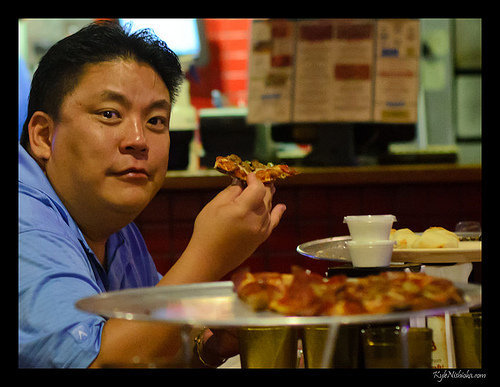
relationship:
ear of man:
[28, 110, 54, 158] [19, 20, 287, 368]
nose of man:
[120, 115, 148, 154] [19, 20, 287, 368]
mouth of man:
[108, 164, 154, 182] [19, 20, 287, 368]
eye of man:
[96, 108, 121, 121] [19, 20, 287, 368]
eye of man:
[144, 116, 168, 126] [19, 20, 287, 368]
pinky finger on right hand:
[268, 202, 288, 233] [195, 169, 286, 271]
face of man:
[68, 60, 170, 209] [19, 20, 287, 368]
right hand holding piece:
[195, 169, 286, 271] [212, 154, 299, 184]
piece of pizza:
[212, 154, 299, 184] [230, 269, 463, 317]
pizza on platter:
[230, 269, 463, 317] [73, 274, 481, 328]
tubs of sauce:
[344, 212, 393, 266] [349, 223, 387, 237]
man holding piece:
[23, 23, 288, 345] [212, 154, 299, 184]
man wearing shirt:
[23, 23, 288, 345] [19, 148, 160, 374]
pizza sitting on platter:
[230, 269, 463, 317] [73, 274, 481, 328]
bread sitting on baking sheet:
[385, 226, 461, 249] [299, 230, 481, 268]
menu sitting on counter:
[251, 19, 418, 123] [161, 163, 489, 185]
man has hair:
[23, 23, 288, 345] [23, 25, 183, 117]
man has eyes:
[23, 23, 288, 345] [99, 108, 165, 130]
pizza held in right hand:
[215, 154, 297, 184] [195, 169, 286, 271]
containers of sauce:
[344, 212, 393, 266] [349, 223, 387, 237]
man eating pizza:
[23, 23, 288, 345] [230, 269, 463, 317]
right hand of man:
[195, 169, 286, 271] [23, 23, 288, 345]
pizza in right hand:
[215, 154, 297, 184] [195, 169, 286, 271]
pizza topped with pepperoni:
[230, 269, 463, 317] [282, 264, 314, 311]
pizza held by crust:
[215, 154, 297, 184] [218, 171, 287, 182]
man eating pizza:
[23, 23, 288, 345] [215, 154, 297, 184]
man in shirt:
[23, 23, 288, 345] [19, 148, 160, 374]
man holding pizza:
[23, 23, 288, 345] [215, 154, 297, 184]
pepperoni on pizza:
[282, 264, 314, 311] [230, 269, 463, 317]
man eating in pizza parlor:
[23, 23, 288, 345] [19, 18, 482, 368]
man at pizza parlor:
[23, 23, 288, 345] [22, 20, 483, 330]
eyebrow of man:
[94, 88, 132, 108] [19, 20, 287, 368]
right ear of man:
[28, 110, 54, 158] [19, 20, 287, 368]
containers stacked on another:
[341, 213, 396, 241] [346, 240, 395, 266]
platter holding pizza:
[74, 274, 467, 353] [230, 269, 463, 317]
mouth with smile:
[108, 164, 154, 182] [105, 160, 163, 189]